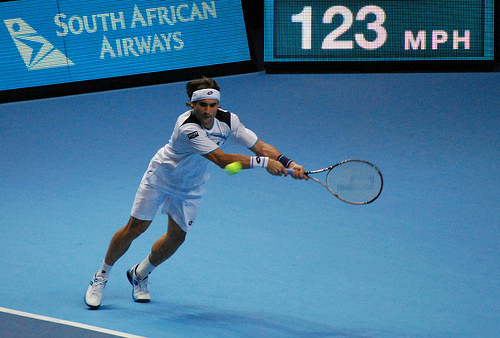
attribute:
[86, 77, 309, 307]
man — playing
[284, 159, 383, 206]
racket — black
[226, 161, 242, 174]
tennis ball — green, yellow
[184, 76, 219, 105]
hair — brown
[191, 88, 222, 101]
headband — white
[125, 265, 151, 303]
tennis shoes — white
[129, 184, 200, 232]
shorts — white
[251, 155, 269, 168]
wristband — white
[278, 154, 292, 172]
wristband — blue, black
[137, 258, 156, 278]
sock — white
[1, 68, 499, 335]
floor — blue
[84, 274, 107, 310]
tennis shoe — white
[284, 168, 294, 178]
handle — blue